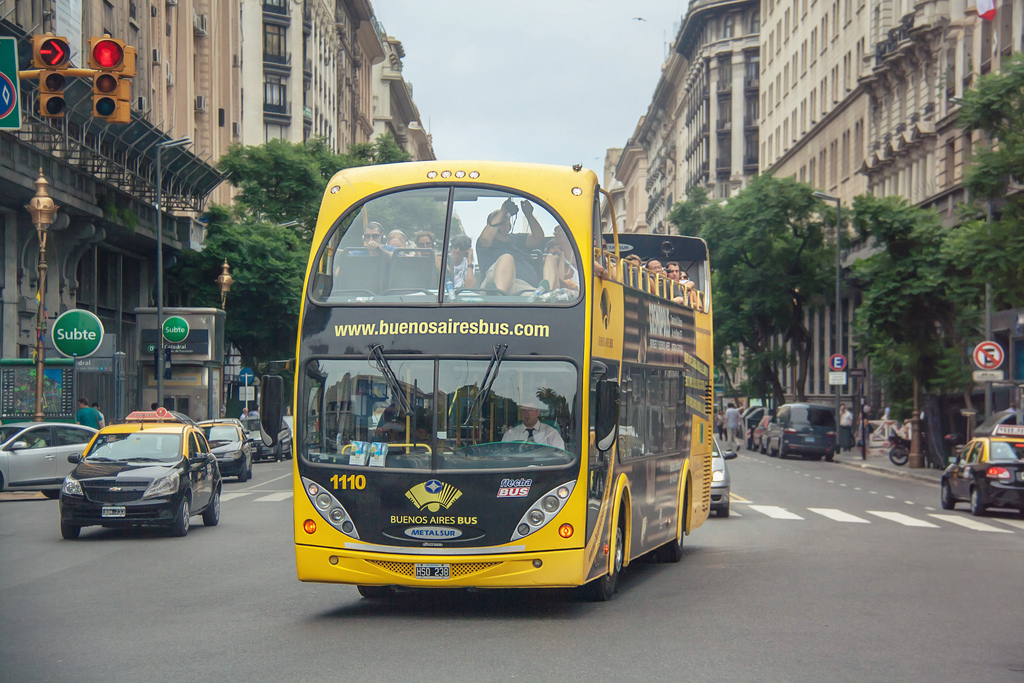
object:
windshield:
[300, 354, 577, 470]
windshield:
[311, 182, 582, 307]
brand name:
[334, 320, 551, 337]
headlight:
[558, 523, 574, 538]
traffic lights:
[34, 37, 70, 118]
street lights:
[159, 136, 193, 413]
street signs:
[972, 340, 1004, 369]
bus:
[295, 161, 715, 612]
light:
[94, 40, 124, 66]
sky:
[443, 9, 623, 139]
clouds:
[458, 21, 622, 145]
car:
[60, 423, 220, 539]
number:
[330, 474, 366, 489]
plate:
[415, 563, 450, 578]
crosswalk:
[731, 505, 1015, 532]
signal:
[90, 39, 137, 123]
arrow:
[40, 41, 63, 65]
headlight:
[303, 520, 317, 534]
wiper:
[464, 344, 509, 425]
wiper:
[367, 344, 414, 416]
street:
[2, 436, 1020, 668]